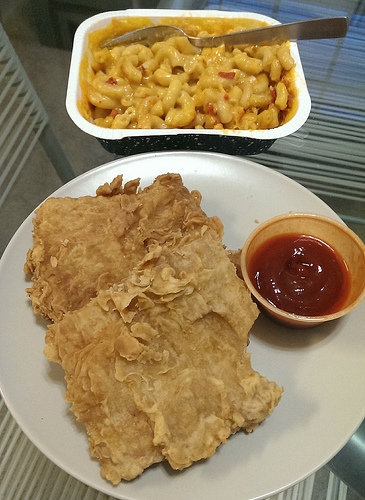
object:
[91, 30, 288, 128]
mac-n-cheese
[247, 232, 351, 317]
ketchup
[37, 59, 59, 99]
ground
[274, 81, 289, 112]
macaroni noodle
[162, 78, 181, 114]
macaroni noodle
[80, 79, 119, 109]
macaroni noodle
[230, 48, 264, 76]
macaroni noodle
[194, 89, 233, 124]
macaroni noodle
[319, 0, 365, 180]
table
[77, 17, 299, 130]
food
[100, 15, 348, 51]
fork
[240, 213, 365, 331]
cup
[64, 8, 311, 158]
bowl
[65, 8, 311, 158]
container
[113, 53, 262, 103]
cheese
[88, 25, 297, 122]
cheesy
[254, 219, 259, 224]
crumb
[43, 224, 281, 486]
meat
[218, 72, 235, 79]
flake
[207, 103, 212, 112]
flake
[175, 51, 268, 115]
mac cheese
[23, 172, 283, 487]
breast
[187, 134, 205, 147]
spot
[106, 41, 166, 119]
mac&cheese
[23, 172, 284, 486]
chicken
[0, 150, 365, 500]
plate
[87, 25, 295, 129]
macaroni